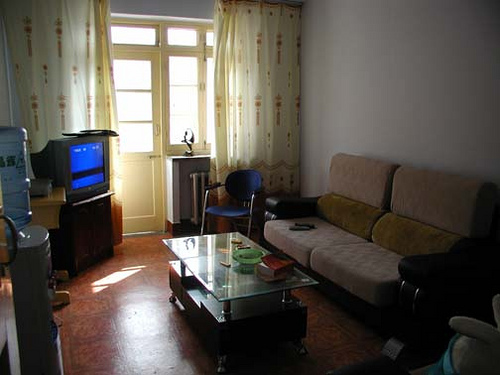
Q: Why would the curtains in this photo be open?
A: To get light.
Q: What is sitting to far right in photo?
A: Sofa.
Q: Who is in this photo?
A: No One.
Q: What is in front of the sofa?
A: Coffee table.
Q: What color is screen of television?
A: Blue.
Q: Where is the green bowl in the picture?
A: On coffee table.